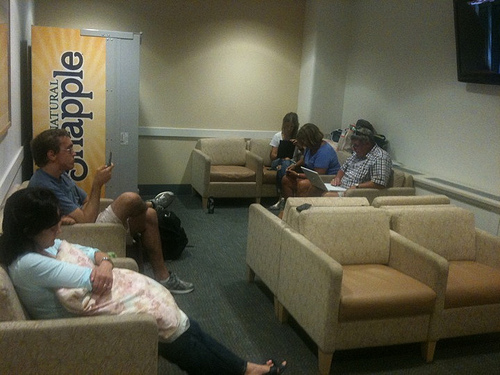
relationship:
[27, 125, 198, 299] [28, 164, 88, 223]
man in shirt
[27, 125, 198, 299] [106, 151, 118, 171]
man with phone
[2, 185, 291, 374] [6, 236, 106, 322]
woman in shirt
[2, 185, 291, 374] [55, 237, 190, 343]
woman holding pillow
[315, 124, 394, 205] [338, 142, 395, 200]
man in shirt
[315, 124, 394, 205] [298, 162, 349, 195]
man with laptop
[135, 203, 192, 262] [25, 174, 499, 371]
backpack on floor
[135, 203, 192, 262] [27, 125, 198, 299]
backpack near man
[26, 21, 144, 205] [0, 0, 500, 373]
vending machine in room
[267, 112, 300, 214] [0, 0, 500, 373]
person in room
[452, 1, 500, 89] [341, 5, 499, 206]
tv on wall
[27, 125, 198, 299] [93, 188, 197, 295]
man with legs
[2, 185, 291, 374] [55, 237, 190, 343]
woman with pillow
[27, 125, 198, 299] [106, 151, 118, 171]
man looking at phone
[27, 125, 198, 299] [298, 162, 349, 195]
man looking at laptop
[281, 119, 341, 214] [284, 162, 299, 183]
woman looking at phone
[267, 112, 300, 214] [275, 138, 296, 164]
person looking at tablet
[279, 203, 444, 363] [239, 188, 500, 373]
chair in group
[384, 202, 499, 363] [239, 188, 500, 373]
chair in group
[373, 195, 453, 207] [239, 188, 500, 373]
chair in group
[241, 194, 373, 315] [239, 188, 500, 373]
chair in group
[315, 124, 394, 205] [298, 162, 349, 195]
man using laptop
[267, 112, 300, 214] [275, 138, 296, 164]
person using tablet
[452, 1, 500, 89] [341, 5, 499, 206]
tv mounted on wall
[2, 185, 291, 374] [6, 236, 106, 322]
woman wearing shirt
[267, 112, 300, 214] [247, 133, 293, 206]
person in chair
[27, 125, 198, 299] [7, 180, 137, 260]
man in chair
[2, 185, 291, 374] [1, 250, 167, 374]
woman in chair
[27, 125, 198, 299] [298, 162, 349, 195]
man on laptop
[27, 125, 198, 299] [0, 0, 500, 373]
man in room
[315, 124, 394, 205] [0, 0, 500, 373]
man in room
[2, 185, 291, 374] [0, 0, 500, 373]
woman in room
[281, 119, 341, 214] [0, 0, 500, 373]
woman in room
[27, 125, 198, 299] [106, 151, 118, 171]
man using phone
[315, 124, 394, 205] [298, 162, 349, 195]
man using computer